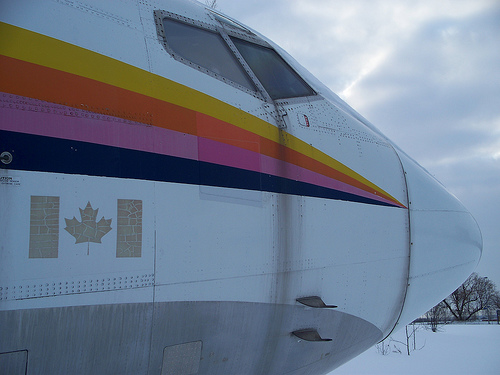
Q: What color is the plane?
A: White.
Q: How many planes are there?
A: One.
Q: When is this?
A: Daytime.